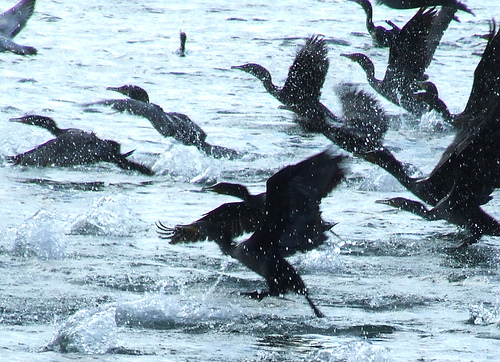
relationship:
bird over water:
[0, 0, 37, 64] [1, 1, 499, 360]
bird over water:
[8, 115, 153, 177] [1, 1, 499, 360]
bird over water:
[103, 85, 238, 161] [1, 1, 499, 360]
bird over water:
[192, 226, 328, 318] [1, 1, 499, 360]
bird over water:
[160, 147, 350, 256] [1, 1, 499, 360]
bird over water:
[235, 33, 351, 124] [1, 1, 499, 360]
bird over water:
[303, 82, 417, 188] [1, 1, 499, 360]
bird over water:
[373, 164, 498, 249] [1, 1, 499, 360]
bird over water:
[359, 92, 499, 208] [1, 1, 499, 360]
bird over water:
[341, 3, 461, 119] [1, 1, 499, 360]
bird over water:
[348, 2, 404, 46] [1, 1, 499, 360]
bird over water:
[373, 4, 463, 10] [1, 1, 499, 360]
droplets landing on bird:
[415, 200, 425, 215] [377, 140, 484, 253]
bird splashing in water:
[103, 85, 238, 161] [1, 1, 499, 360]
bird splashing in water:
[1, 115, 157, 173] [1, 1, 499, 360]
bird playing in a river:
[103, 85, 238, 161] [13, 216, 156, 353]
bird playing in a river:
[162, 144, 357, 245] [13, 216, 156, 353]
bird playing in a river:
[373, 164, 498, 249] [13, 216, 156, 353]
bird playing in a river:
[1, 115, 157, 173] [13, 216, 156, 353]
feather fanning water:
[305, 293, 325, 317] [1, 1, 499, 360]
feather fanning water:
[122, 160, 152, 177] [1, 1, 499, 360]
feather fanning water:
[198, 138, 235, 160] [1, 1, 499, 360]